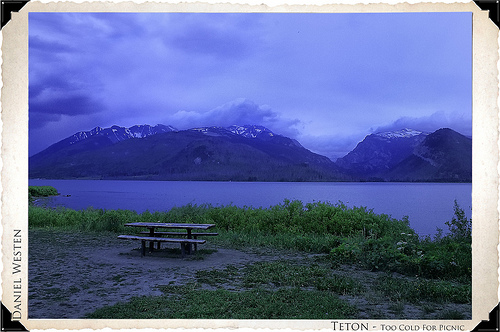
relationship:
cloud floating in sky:
[28, 14, 470, 131] [28, 12, 473, 143]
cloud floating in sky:
[376, 107, 473, 133] [28, 12, 473, 143]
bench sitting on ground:
[118, 220, 216, 257] [30, 224, 468, 319]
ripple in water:
[360, 181, 470, 193] [30, 177, 472, 237]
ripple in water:
[331, 194, 473, 205] [30, 177, 472, 237]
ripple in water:
[198, 184, 319, 191] [30, 177, 472, 237]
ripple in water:
[48, 192, 175, 207] [30, 177, 472, 237]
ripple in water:
[377, 202, 469, 219] [30, 177, 472, 237]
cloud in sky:
[28, 14, 470, 131] [29, 11, 470, 158]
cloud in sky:
[28, 14, 470, 131] [29, 12, 469, 129]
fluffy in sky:
[77, 101, 352, 218] [113, 32, 363, 115]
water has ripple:
[30, 177, 472, 237] [48, 192, 175, 207]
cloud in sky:
[28, 14, 470, 131] [28, 12, 473, 143]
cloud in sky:
[28, 14, 470, 131] [29, 10, 473, 180]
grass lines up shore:
[34, 200, 470, 330] [32, 216, 466, 330]